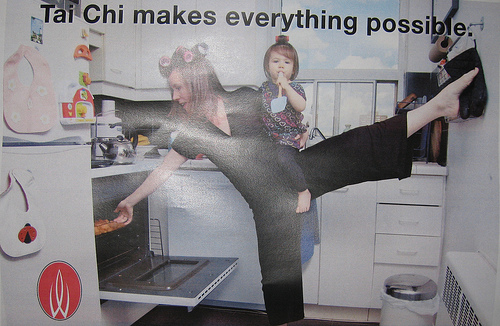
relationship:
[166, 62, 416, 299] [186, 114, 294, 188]
woman wearing shirt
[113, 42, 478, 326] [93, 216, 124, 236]
woman grabbing food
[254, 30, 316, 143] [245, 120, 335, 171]
child on woman's hip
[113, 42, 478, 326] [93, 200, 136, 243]
woman grabbing food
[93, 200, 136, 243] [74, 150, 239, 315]
food from oven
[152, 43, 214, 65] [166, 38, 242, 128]
curlers in woman's hair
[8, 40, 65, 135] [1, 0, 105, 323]
bib hanging on fridge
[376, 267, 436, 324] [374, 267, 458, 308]
trash can with silver lid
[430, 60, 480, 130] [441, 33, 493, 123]
woman's foot resting on oven mitt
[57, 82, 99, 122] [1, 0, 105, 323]
barn toy on fridge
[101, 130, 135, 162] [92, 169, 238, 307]
tea kettle on oven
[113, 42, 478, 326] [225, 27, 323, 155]
woman holding her child